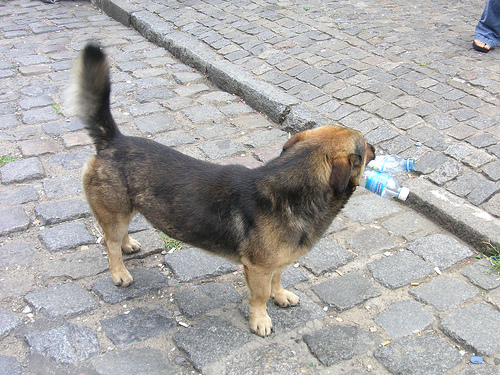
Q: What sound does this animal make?
A: He barks.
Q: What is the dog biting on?
A: Water bottles.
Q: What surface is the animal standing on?
A: Brick.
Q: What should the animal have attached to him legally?
A: A leash.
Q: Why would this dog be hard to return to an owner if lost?
A: No tags.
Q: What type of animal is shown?
A: A dog.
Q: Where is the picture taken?
A: A street.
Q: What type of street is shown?
A: Cobbled.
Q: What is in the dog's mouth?
A: Bottles.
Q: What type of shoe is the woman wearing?
A: A flip flop.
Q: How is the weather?
A: Sunny.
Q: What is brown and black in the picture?
A: A dog.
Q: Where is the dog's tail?
A: Straight up.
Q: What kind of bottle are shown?
A: Water.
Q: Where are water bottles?
A: In dog's mouth.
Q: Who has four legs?
A: The dog.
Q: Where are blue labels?
A: On water bottles.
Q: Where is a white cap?
A: On water bottle.